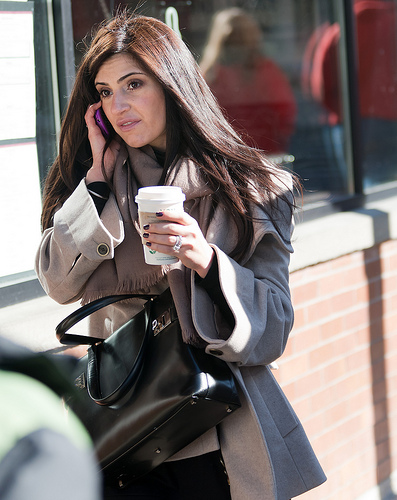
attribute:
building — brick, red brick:
[0, 0, 396, 499]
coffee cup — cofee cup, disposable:
[133, 185, 184, 267]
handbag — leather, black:
[28, 286, 240, 495]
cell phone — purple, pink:
[94, 106, 112, 139]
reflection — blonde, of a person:
[198, 10, 297, 156]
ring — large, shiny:
[171, 234, 184, 255]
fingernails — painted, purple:
[155, 210, 165, 219]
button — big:
[96, 244, 110, 256]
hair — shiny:
[41, 7, 303, 258]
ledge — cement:
[0, 197, 396, 367]